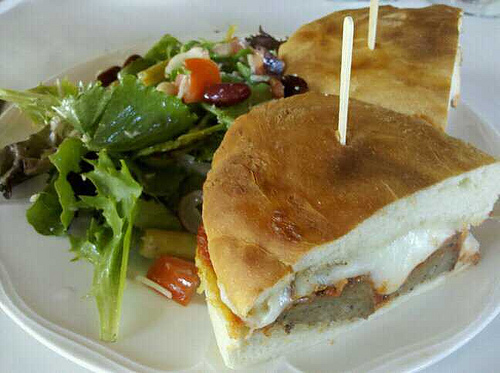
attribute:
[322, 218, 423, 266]
cheese — mozzarella, white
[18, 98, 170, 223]
leaf — green, lettuce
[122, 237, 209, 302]
tomato — red, diced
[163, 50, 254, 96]
pepper — red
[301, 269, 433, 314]
meat — gray, dark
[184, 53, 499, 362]
sandwich — cut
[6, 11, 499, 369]
plate — white, sitting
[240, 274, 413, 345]
meatball — halve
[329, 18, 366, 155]
pick — tooth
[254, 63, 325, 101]
olive — green, black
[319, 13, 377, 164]
stick — wooden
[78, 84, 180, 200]
lettuce — green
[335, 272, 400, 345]
ketchup — red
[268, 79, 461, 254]
bread — white